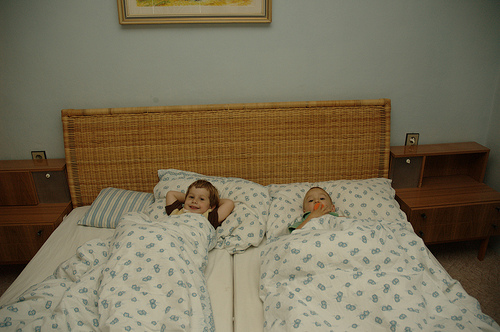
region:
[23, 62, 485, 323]
two children laying in a bed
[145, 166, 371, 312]
two children laying down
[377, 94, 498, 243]
a wooden night stand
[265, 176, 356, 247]
a little boy with a pacifier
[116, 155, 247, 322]
a child with their arms behind their head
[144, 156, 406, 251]
two pillows on a bed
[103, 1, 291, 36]
the edge of a picture frame on the wall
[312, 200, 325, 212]
an orange pacifier in the baby's mouth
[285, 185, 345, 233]
a baby boy sucking an orange pacifier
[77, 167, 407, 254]
three pillows on the bed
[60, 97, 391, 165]
the headboard of a king size bed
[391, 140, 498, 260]
a wooden table beside the bed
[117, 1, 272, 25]
the bottom of a picture in a frame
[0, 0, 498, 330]
a king size bed in the bedroom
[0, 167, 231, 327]
a young boy smiling while lying down in the bed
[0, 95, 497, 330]
two boys lying down the backs in a bed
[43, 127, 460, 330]
TWO KIDS LAYING ON A BED.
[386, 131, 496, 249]
A LARGE NIGHT STAND.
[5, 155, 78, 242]
A SECOND LARGE NIGHT STAND.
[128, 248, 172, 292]
BLUE DESIGNS ON THE BLANKET.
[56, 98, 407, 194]
A HEAD BOARD MADE OF STRAW.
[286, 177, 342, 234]
THE BABY HAS A PACIFIER.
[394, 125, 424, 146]
A PICTURE ON THE TABLE.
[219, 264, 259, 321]
TWO BEDS PUT TOGETHER.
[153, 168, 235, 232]
THE BOY IS SMILING.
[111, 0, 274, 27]
A FRAMED PICTURE ABOVE THE BED.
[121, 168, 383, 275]
kids laying under comforters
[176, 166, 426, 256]
kids laying on pillows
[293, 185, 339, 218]
a kid holding onto a pacifier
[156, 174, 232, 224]
a kid laying on his arms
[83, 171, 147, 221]
a small pillow laying on a bed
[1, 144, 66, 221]
a night stand standing near a bed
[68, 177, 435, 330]
a bed underneath two kids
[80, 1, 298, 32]
a picture hanging on a wall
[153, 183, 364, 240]
Kids laying down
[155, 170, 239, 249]
Child with hands behind head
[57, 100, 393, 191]
A wooden headboard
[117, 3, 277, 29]
Picture frame on the wall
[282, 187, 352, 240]
Child with binky in mouth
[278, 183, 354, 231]
Child laying under sheets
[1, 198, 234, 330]
One white mattress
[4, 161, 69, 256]
Wooden cupboards next to bed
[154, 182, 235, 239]
Child with head on pillow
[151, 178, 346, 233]
Children laying on pillow